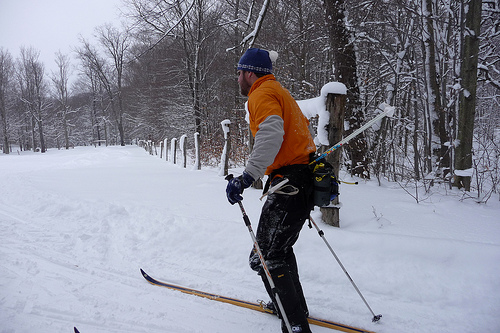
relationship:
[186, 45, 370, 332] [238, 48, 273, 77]
skier has hat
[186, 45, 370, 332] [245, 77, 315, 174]
skier has sweater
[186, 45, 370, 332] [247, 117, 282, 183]
skier has sleeve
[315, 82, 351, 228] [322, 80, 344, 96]
post has snow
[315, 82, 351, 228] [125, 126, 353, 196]
post for fence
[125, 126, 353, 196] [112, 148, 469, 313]
fence in snow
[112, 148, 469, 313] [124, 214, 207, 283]
snow has footprints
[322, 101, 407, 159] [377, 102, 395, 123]
pick for ice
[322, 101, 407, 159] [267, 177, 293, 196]
pick has handle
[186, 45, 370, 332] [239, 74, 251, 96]
skier has beard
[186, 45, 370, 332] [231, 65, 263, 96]
skier has face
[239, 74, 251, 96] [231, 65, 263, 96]
beard on face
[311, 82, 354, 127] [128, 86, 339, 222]
post of fence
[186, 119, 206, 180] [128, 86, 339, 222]
post of fence